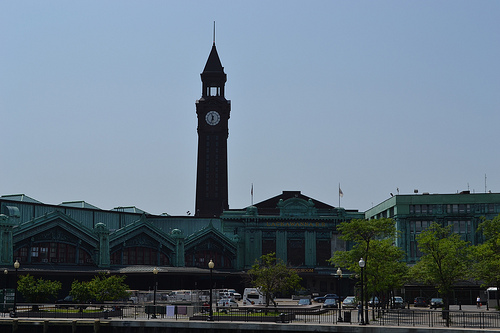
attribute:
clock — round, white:
[203, 110, 220, 129]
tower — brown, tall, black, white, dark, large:
[192, 13, 237, 221]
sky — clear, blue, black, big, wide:
[2, 5, 498, 214]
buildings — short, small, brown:
[3, 190, 499, 293]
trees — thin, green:
[326, 215, 499, 308]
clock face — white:
[206, 107, 221, 128]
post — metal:
[356, 271, 373, 330]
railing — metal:
[279, 308, 492, 326]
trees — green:
[326, 207, 493, 330]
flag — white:
[336, 183, 344, 199]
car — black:
[428, 293, 443, 311]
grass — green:
[196, 311, 286, 322]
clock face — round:
[203, 109, 223, 132]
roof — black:
[238, 188, 340, 209]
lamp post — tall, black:
[351, 251, 370, 329]